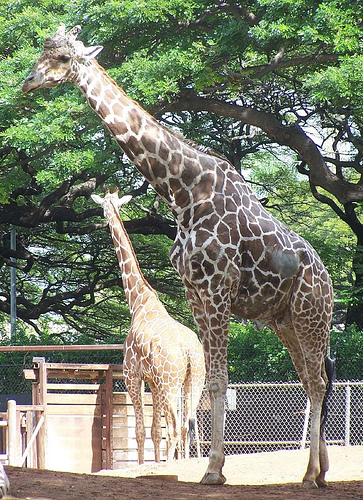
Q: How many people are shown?
A: None.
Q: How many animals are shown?
A: Two.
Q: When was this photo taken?
A: Daytime.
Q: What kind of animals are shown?
A: Giraffes.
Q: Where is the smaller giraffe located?
A: On the left.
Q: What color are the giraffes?
A: Brown & white.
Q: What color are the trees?
A: Green.